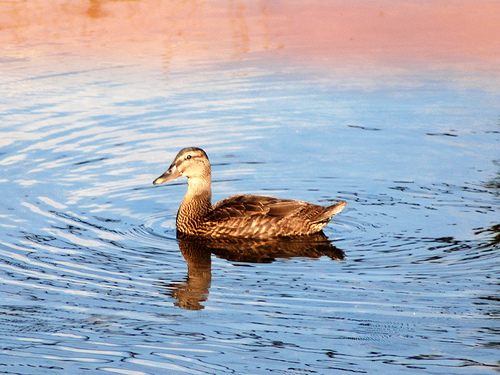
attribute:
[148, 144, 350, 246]
duck — brown, floating, single, alone, singular, 'swimming', paddling, various brown shades, moving slowly, mallard, in profile, tan, brown+tan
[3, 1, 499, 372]
water — reflecting, blue, pink, blue+pink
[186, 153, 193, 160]
eye — black, circular, round, singular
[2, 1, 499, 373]
scene — sunny, outdoors, in daytime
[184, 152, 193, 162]
rim — dark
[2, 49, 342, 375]
sunlight — reflecting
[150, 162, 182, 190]
beak — brown, bill, leathery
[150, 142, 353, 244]
mallard — female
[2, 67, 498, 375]
pond — blue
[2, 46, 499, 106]
haze — purple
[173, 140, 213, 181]
highlights — black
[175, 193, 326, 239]
feathers — slightly shimmery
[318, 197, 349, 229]
tail — reflected